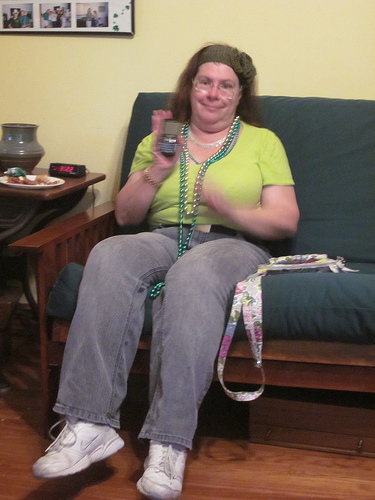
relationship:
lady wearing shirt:
[21, 44, 303, 499] [126, 121, 295, 223]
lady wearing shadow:
[21, 44, 303, 499] [33, 420, 125, 479]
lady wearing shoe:
[21, 44, 303, 499] [135, 439, 186, 498]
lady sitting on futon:
[21, 44, 303, 499] [8, 91, 374, 438]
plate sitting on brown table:
[0, 167, 65, 187] [0, 165, 106, 201]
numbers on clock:
[55, 164, 72, 172] [45, 162, 88, 178]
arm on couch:
[6, 194, 126, 255] [9, 86, 362, 455]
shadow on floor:
[25, 455, 117, 497] [0, 360, 372, 497]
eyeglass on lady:
[189, 78, 243, 98] [21, 44, 303, 499]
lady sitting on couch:
[21, 40, 302, 498] [9, 86, 362, 455]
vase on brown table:
[2, 122, 46, 171] [0, 165, 106, 201]